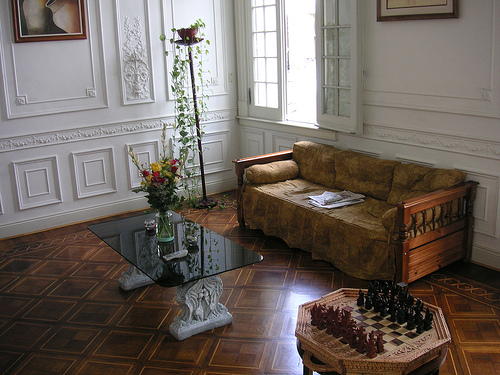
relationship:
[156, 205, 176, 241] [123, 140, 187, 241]
vase filled with bouquet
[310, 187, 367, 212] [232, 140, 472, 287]
paper on couch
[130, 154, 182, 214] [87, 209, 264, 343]
flowers on table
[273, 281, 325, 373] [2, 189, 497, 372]
light on floor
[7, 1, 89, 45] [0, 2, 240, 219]
picture on wall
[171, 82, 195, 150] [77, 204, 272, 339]
leaves on table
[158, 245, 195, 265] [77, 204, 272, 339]
controller on table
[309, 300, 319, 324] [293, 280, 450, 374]
chess on chess table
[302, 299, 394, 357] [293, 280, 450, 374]
chess pieces on chess table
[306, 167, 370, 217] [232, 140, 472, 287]
white papers on couch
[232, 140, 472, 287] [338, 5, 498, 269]
couch against wall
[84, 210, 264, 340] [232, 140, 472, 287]
coffee table in front of couch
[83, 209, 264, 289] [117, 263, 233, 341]
top on base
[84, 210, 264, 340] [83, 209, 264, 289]
coffee table with top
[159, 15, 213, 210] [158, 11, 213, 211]
plant has vines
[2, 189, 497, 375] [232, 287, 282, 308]
floor has square pattern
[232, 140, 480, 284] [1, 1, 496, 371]
couch in living room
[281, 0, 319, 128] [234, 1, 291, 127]
opened window with shutter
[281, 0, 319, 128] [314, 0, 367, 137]
opened window with shutter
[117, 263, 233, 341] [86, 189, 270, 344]
base of table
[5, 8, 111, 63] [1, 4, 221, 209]
frame on wall